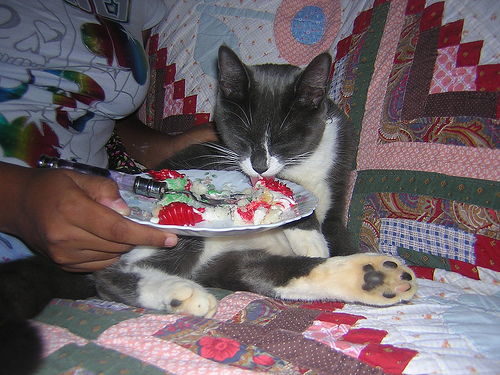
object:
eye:
[223, 115, 251, 132]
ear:
[215, 45, 253, 108]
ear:
[289, 51, 332, 109]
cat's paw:
[335, 243, 424, 319]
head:
[207, 40, 333, 185]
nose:
[248, 146, 270, 174]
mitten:
[282, 227, 331, 258]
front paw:
[282, 227, 330, 260]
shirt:
[1, 1, 168, 261]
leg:
[221, 240, 353, 303]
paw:
[350, 248, 422, 311]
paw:
[165, 279, 218, 322]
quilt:
[42, 2, 498, 375]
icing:
[249, 177, 293, 207]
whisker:
[289, 149, 336, 175]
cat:
[95, 45, 414, 318]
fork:
[37, 153, 246, 207]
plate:
[104, 168, 316, 237]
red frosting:
[158, 201, 205, 227]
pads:
[360, 252, 415, 306]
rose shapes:
[193, 334, 243, 362]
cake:
[123, 161, 296, 227]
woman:
[0, 0, 219, 321]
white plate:
[112, 159, 315, 239]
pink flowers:
[241, 186, 293, 228]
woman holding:
[0, 0, 183, 305]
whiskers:
[189, 137, 260, 174]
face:
[213, 47, 333, 179]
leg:
[91, 242, 165, 313]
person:
[0, 2, 222, 277]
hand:
[145, 120, 223, 172]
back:
[134, 127, 233, 187]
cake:
[149, 174, 291, 219]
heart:
[12, 32, 43, 60]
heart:
[31, 19, 65, 42]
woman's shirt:
[0, 7, 157, 261]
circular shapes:
[272, 2, 349, 58]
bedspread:
[30, 295, 421, 375]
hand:
[18, 162, 180, 275]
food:
[132, 164, 297, 231]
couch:
[47, 0, 498, 375]